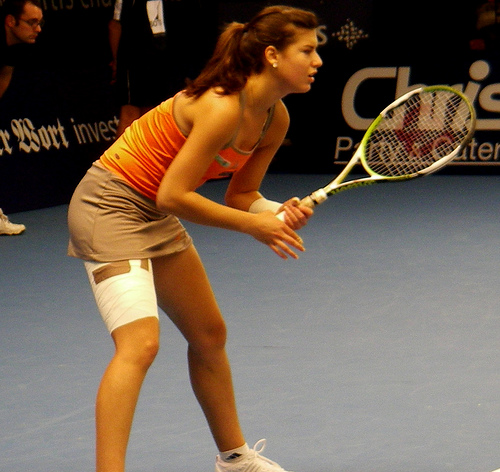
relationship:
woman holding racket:
[56, 3, 339, 469] [313, 80, 483, 225]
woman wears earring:
[56, 3, 339, 469] [267, 61, 281, 72]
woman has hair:
[56, 3, 339, 469] [246, 26, 282, 41]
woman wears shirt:
[56, 3, 339, 469] [110, 96, 200, 165]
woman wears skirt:
[56, 3, 339, 469] [77, 190, 153, 251]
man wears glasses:
[3, 3, 46, 244] [17, 16, 43, 26]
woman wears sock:
[56, 3, 339, 469] [215, 442, 255, 459]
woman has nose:
[56, 3, 339, 469] [313, 50, 327, 69]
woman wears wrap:
[56, 3, 339, 469] [94, 262, 162, 334]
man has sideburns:
[3, 3, 46, 244] [8, 14, 23, 34]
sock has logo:
[215, 442, 255, 459] [222, 450, 243, 463]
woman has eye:
[56, 3, 339, 469] [300, 43, 316, 59]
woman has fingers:
[56, 3, 339, 469] [266, 223, 310, 264]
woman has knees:
[56, 3, 339, 469] [116, 323, 246, 364]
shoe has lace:
[216, 460, 288, 471] [251, 430, 275, 454]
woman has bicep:
[56, 3, 339, 469] [175, 140, 221, 176]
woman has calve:
[56, 3, 339, 469] [188, 363, 220, 431]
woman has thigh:
[56, 3, 339, 469] [165, 271, 212, 317]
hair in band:
[246, 26, 282, 41] [241, 19, 252, 32]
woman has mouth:
[56, 3, 339, 469] [302, 69, 325, 86]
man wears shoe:
[3, 3, 46, 244] [1, 209, 33, 240]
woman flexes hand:
[56, 3, 339, 469] [248, 209, 299, 253]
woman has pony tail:
[56, 3, 339, 469] [149, 16, 266, 128]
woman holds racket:
[56, 3, 339, 469] [313, 80, 483, 225]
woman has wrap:
[56, 3, 339, 469] [94, 262, 162, 334]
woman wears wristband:
[56, 3, 339, 469] [256, 198, 282, 216]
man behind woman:
[3, 3, 46, 244] [56, 3, 339, 469]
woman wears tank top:
[56, 3, 339, 469] [88, 96, 264, 216]